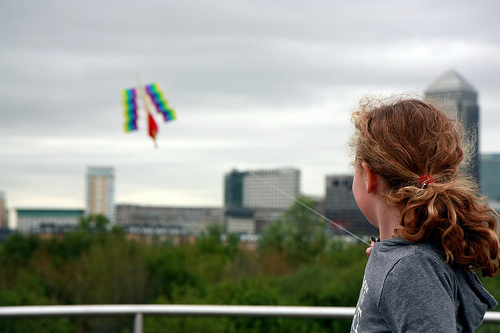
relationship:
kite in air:
[80, 76, 216, 163] [38, 37, 106, 128]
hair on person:
[349, 92, 499, 275] [329, 90, 498, 330]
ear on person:
[353, 153, 379, 204] [358, 111, 453, 252]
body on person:
[344, 235, 495, 331] [342, 94, 492, 330]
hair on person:
[349, 92, 499, 278] [342, 94, 492, 330]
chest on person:
[353, 244, 398, 331] [342, 94, 492, 330]